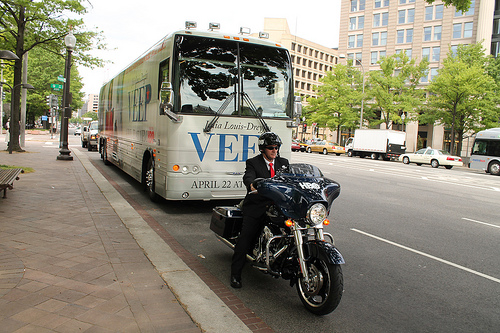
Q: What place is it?
A: It is a street.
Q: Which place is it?
A: It is a street.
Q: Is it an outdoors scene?
A: Yes, it is outdoors.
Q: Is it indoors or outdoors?
A: It is outdoors.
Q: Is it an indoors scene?
A: No, it is outdoors.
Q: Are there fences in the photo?
A: No, there are no fences.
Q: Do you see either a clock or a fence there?
A: No, there are no fences or clocks.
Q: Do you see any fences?
A: No, there are no fences.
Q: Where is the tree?
A: The tree is on the side walk.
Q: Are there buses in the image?
A: Yes, there is a bus.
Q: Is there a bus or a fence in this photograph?
A: Yes, there is a bus.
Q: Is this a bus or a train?
A: This is a bus.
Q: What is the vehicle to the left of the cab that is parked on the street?
A: The vehicle is a bus.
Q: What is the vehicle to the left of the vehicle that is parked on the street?
A: The vehicle is a bus.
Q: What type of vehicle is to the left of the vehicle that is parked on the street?
A: The vehicle is a bus.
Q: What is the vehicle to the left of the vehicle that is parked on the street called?
A: The vehicle is a bus.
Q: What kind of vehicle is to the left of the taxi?
A: The vehicle is a bus.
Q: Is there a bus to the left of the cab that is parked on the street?
A: Yes, there is a bus to the left of the cab.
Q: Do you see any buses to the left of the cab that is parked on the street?
A: Yes, there is a bus to the left of the cab.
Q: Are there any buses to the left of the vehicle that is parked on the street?
A: Yes, there is a bus to the left of the cab.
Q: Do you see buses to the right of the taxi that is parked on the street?
A: No, the bus is to the left of the taxi.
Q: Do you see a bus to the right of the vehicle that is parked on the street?
A: No, the bus is to the left of the taxi.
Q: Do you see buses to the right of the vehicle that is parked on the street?
A: No, the bus is to the left of the taxi.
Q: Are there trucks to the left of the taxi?
A: No, there is a bus to the left of the taxi.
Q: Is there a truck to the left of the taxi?
A: No, there is a bus to the left of the taxi.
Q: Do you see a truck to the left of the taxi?
A: No, there is a bus to the left of the taxi.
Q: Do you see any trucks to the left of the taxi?
A: No, there is a bus to the left of the taxi.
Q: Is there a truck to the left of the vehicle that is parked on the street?
A: No, there is a bus to the left of the taxi.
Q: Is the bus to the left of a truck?
A: No, the bus is to the left of the taxi cab.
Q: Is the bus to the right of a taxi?
A: No, the bus is to the left of a taxi.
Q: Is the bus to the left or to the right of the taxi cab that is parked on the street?
A: The bus is to the left of the cab.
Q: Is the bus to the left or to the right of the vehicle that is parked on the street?
A: The bus is to the left of the cab.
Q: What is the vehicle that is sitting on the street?
A: The vehicle is a bus.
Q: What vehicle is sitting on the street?
A: The vehicle is a bus.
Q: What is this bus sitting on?
A: The bus is sitting on the street.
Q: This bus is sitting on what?
A: The bus is sitting on the street.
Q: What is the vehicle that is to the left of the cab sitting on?
A: The bus is sitting on the street.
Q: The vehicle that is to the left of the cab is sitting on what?
A: The bus is sitting on the street.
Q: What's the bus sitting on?
A: The bus is sitting on the street.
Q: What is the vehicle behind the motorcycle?
A: The vehicle is a bus.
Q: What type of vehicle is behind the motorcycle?
A: The vehicle is a bus.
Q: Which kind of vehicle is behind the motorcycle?
A: The vehicle is a bus.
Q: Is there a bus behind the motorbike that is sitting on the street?
A: Yes, there is a bus behind the motorbike.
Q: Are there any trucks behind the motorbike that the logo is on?
A: No, there is a bus behind the motorbike.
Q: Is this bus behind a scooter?
A: No, the bus is behind a motorcycle.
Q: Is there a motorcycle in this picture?
A: Yes, there is a motorcycle.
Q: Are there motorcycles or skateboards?
A: Yes, there is a motorcycle.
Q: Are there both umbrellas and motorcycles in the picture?
A: No, there is a motorcycle but no umbrellas.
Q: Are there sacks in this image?
A: No, there are no sacks.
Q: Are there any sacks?
A: No, there are no sacks.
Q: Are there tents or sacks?
A: No, there are no sacks or tents.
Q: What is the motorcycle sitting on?
A: The motorcycle is sitting on the street.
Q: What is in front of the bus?
A: The motorcycle is in front of the bus.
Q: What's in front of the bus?
A: The motorcycle is in front of the bus.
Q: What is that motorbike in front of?
A: The motorbike is in front of the bus.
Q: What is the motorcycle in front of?
A: The motorbike is in front of the bus.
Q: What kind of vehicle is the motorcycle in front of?
A: The motorcycle is in front of the bus.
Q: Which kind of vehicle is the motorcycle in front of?
A: The motorcycle is in front of the bus.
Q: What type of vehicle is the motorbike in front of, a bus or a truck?
A: The motorbike is in front of a bus.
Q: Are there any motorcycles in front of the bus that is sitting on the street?
A: Yes, there is a motorcycle in front of the bus.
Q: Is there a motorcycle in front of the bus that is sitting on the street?
A: Yes, there is a motorcycle in front of the bus.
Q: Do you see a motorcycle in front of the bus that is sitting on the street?
A: Yes, there is a motorcycle in front of the bus.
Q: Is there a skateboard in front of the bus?
A: No, there is a motorcycle in front of the bus.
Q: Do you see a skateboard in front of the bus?
A: No, there is a motorcycle in front of the bus.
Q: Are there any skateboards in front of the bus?
A: No, there is a motorcycle in front of the bus.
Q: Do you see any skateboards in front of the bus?
A: No, there is a motorcycle in front of the bus.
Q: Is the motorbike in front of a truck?
A: No, the motorbike is in front of a bus.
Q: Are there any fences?
A: No, there are no fences.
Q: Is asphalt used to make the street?
A: Yes, the street is made of asphalt.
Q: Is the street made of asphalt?
A: Yes, the street is made of asphalt.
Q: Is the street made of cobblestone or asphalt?
A: The street is made of asphalt.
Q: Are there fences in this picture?
A: No, there are no fences.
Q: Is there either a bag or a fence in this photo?
A: No, there are no fences or bags.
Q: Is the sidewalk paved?
A: Yes, the sidewalk is paved.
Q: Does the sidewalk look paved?
A: Yes, the sidewalk is paved.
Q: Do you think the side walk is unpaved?
A: No, the side walk is paved.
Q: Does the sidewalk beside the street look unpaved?
A: No, the sidewalk is paved.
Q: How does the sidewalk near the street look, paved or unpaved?
A: The sidewalk is paved.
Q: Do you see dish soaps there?
A: No, there are no dish soaps.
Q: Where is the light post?
A: The light post is on the sidewalk.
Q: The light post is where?
A: The light post is on the sidewalk.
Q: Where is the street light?
A: The light post is on the sidewalk.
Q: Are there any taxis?
A: Yes, there is a taxi.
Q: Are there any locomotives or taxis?
A: Yes, there is a taxi.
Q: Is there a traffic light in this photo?
A: No, there are no traffic lights.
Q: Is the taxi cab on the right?
A: Yes, the taxi cab is on the right of the image.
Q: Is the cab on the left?
A: No, the cab is on the right of the image.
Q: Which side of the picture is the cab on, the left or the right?
A: The cab is on the right of the image.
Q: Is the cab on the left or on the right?
A: The cab is on the right of the image.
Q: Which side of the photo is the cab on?
A: The cab is on the right of the image.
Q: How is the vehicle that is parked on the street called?
A: The vehicle is a taxi.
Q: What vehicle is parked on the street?
A: The vehicle is a taxi.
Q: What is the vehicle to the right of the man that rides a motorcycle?
A: The vehicle is a taxi.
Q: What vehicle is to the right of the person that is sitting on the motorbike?
A: The vehicle is a taxi.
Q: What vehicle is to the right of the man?
A: The vehicle is a taxi.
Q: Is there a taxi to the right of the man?
A: Yes, there is a taxi to the right of the man.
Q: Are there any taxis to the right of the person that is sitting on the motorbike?
A: Yes, there is a taxi to the right of the man.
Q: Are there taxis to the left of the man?
A: No, the taxi is to the right of the man.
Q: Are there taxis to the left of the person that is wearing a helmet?
A: No, the taxi is to the right of the man.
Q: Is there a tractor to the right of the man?
A: No, there is a taxi to the right of the man.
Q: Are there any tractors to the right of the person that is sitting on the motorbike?
A: No, there is a taxi to the right of the man.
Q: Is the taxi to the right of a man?
A: Yes, the taxi is to the right of a man.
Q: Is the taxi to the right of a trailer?
A: No, the taxi is to the right of a man.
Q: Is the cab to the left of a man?
A: No, the cab is to the right of a man.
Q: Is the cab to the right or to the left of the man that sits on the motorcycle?
A: The cab is to the right of the man.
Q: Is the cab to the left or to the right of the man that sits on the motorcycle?
A: The cab is to the right of the man.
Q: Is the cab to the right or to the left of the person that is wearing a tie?
A: The cab is to the right of the man.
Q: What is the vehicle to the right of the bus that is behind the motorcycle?
A: The vehicle is a taxi.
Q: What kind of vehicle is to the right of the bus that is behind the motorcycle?
A: The vehicle is a taxi.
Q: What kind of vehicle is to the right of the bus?
A: The vehicle is a taxi.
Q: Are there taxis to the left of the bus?
A: No, the taxi is to the right of the bus.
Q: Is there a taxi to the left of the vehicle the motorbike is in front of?
A: No, the taxi is to the right of the bus.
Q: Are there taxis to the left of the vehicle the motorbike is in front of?
A: No, the taxi is to the right of the bus.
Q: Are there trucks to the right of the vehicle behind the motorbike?
A: No, there is a taxi to the right of the bus.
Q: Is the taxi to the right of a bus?
A: Yes, the taxi is to the right of a bus.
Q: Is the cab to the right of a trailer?
A: No, the cab is to the right of a bus.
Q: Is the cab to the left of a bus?
A: No, the cab is to the right of a bus.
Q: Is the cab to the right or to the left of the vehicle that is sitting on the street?
A: The cab is to the right of the bus.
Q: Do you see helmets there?
A: Yes, there is a helmet.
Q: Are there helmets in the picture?
A: Yes, there is a helmet.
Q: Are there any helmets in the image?
A: Yes, there is a helmet.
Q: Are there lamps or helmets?
A: Yes, there is a helmet.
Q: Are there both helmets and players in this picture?
A: No, there is a helmet but no players.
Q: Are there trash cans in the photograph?
A: No, there are no trash cans.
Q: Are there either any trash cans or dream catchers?
A: No, there are no trash cans or dream catchers.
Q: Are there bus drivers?
A: No, there are no bus drivers.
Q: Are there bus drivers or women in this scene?
A: No, there are no bus drivers or women.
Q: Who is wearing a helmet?
A: The man is wearing a helmet.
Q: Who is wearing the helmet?
A: The man is wearing a helmet.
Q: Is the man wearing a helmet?
A: Yes, the man is wearing a helmet.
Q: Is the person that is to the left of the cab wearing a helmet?
A: Yes, the man is wearing a helmet.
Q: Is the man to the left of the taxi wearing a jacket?
A: No, the man is wearing a helmet.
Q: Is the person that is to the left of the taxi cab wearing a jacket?
A: No, the man is wearing a helmet.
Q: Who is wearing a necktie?
A: The man is wearing a necktie.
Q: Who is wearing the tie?
A: The man is wearing a necktie.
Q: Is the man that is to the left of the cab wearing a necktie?
A: Yes, the man is wearing a necktie.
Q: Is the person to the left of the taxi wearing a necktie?
A: Yes, the man is wearing a necktie.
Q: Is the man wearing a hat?
A: No, the man is wearing a necktie.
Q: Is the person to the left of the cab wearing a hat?
A: No, the man is wearing a necktie.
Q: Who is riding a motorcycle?
A: The man is riding a motorcycle.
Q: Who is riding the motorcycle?
A: The man is riding a motorcycle.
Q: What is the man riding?
A: The man is riding a motorcycle.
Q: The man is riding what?
A: The man is riding a motorcycle.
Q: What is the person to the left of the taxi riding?
A: The man is riding a motorcycle.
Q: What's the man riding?
A: The man is riding a motorcycle.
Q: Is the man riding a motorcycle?
A: Yes, the man is riding a motorcycle.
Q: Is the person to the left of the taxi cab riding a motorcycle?
A: Yes, the man is riding a motorcycle.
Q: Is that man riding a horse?
A: No, the man is riding a motorcycle.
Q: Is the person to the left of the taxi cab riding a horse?
A: No, the man is riding a motorcycle.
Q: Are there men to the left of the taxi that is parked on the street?
A: Yes, there is a man to the left of the taxi.